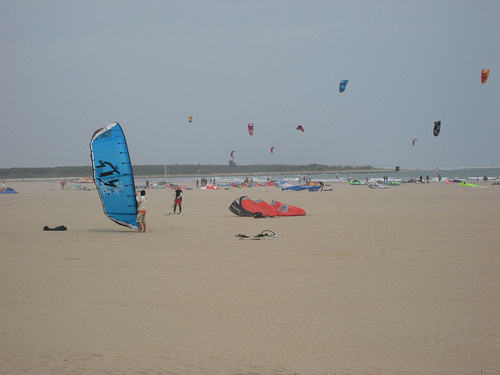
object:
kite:
[339, 79, 349, 94]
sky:
[1, 0, 500, 170]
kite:
[480, 68, 490, 84]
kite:
[432, 120, 442, 137]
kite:
[411, 139, 418, 146]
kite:
[296, 124, 305, 132]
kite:
[248, 122, 254, 135]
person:
[134, 189, 148, 233]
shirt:
[135, 195, 148, 212]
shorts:
[135, 210, 147, 223]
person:
[172, 186, 184, 215]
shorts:
[174, 199, 183, 206]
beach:
[0, 180, 499, 375]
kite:
[88, 118, 141, 231]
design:
[95, 159, 124, 198]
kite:
[227, 195, 306, 219]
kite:
[281, 185, 322, 193]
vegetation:
[1, 163, 388, 179]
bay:
[132, 167, 500, 182]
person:
[425, 174, 430, 183]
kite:
[188, 115, 193, 122]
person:
[420, 174, 424, 183]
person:
[143, 178, 150, 189]